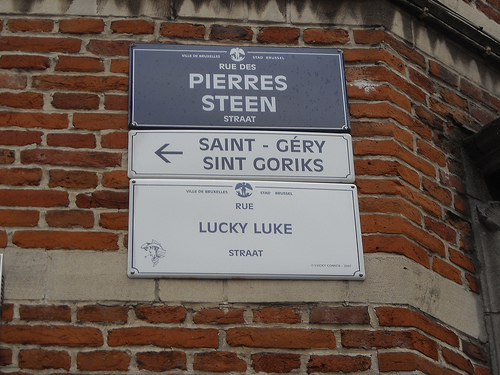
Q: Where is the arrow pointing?
A: Left.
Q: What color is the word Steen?
A: White.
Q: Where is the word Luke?
A: After lucky.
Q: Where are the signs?
A: On a wall.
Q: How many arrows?
A: 1.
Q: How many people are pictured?
A: Zero.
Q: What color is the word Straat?
A: Blue.